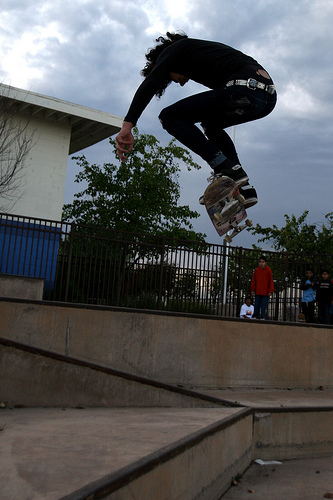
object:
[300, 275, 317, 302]
jacket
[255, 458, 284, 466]
paper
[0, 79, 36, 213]
branches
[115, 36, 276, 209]
boy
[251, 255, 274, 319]
boy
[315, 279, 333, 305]
sweater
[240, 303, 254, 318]
top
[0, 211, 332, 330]
fence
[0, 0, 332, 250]
clouds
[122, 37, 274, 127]
black shirt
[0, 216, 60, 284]
blue wall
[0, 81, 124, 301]
building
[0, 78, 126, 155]
roof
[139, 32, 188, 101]
hair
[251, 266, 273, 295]
red jacket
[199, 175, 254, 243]
skateboard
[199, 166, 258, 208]
feet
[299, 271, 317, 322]
boys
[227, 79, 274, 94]
belt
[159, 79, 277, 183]
pants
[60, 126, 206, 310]
trees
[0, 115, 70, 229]
wall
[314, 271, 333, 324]
boys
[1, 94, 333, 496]
park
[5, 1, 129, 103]
blue sky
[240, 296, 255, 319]
kid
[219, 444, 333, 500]
floor